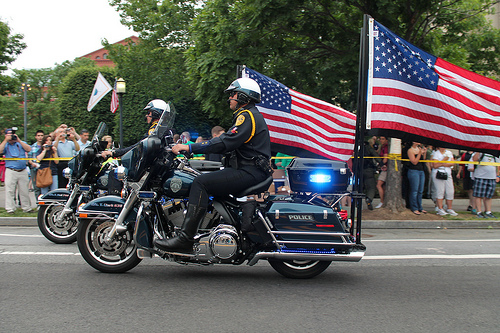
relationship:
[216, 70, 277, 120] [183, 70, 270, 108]
cop has helmet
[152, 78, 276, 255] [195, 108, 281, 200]
cop has uniform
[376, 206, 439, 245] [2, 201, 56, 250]
sidewalk by corner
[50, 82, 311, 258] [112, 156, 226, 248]
men on motorcycles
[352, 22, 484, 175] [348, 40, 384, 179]
flag on pole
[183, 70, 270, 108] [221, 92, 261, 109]
helmet on head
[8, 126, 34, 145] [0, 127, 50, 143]
camera in hands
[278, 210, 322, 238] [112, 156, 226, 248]
logo on motorcycles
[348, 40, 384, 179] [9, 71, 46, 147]
pole has light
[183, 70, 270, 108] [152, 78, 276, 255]
helmet on cop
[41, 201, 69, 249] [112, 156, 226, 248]
tire on motorcycles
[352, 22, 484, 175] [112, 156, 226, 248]
flag on motorcycles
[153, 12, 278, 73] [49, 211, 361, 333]
trees by road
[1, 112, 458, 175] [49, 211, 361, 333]
crowd by road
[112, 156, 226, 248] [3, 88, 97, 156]
motorcycles with man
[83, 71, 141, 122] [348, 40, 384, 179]
flags on pole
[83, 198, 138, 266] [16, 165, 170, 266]
wheel in front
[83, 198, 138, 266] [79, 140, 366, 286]
wheel in front of motorcycle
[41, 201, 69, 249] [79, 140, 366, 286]
tire in front of motorcycle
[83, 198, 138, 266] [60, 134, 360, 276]
wheel in front of motorcycle